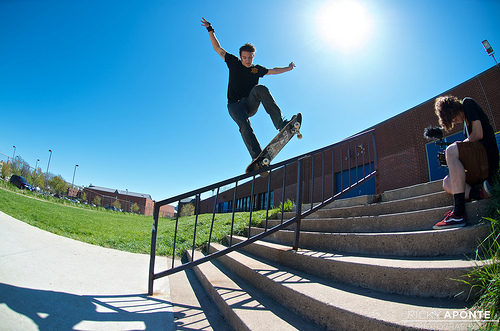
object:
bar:
[147, 201, 159, 296]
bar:
[170, 198, 180, 269]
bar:
[188, 191, 200, 262]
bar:
[203, 184, 218, 256]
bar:
[261, 174, 272, 233]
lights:
[35, 141, 89, 171]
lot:
[16, 171, 144, 210]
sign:
[327, 135, 382, 162]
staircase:
[238, 171, 497, 328]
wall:
[396, 130, 419, 169]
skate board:
[244, 111, 302, 176]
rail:
[148, 127, 381, 303]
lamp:
[479, 32, 499, 68]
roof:
[408, 66, 496, 112]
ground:
[4, 240, 153, 329]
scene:
[0, 0, 500, 330]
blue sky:
[1, 5, 174, 76]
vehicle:
[8, 171, 32, 191]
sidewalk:
[0, 210, 178, 329]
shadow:
[0, 276, 180, 330]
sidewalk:
[1, 259, 131, 330]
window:
[331, 163, 376, 200]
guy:
[199, 15, 299, 178]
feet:
[246, 113, 300, 179]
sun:
[298, 0, 391, 62]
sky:
[1, 1, 499, 203]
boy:
[430, 93, 498, 229]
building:
[167, 51, 497, 211]